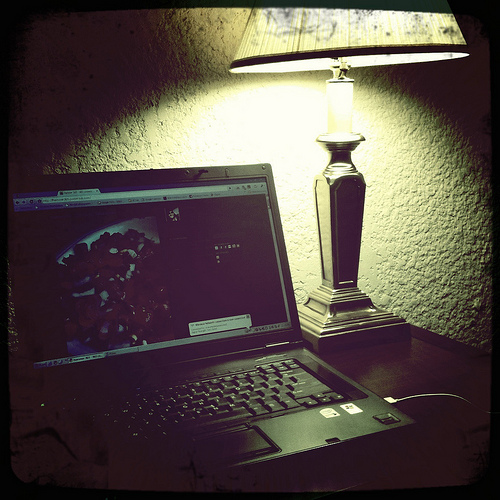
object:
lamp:
[226, 9, 471, 74]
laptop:
[0, 163, 415, 500]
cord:
[396, 393, 490, 415]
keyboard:
[82, 357, 344, 459]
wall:
[1, 4, 494, 359]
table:
[0, 322, 494, 500]